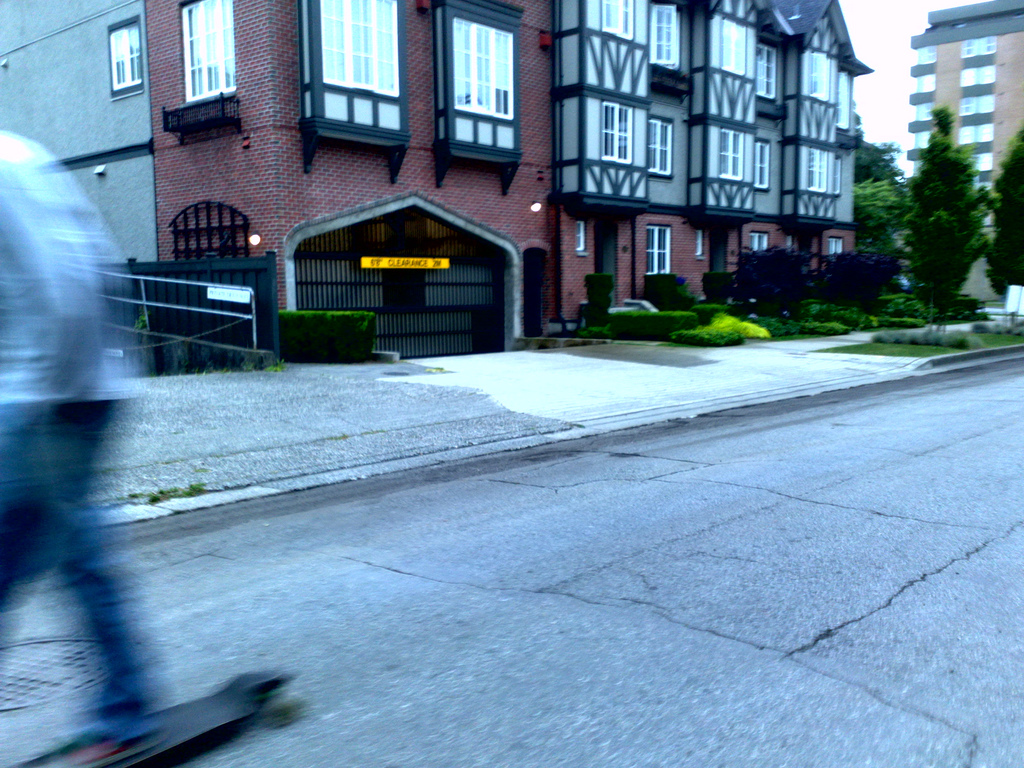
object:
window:
[646, 224, 671, 275]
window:
[695, 230, 703, 256]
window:
[577, 221, 586, 252]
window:
[109, 21, 144, 93]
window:
[600, 100, 632, 164]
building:
[0, 0, 874, 378]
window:
[647, 118, 672, 177]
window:
[718, 128, 743, 181]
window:
[751, 141, 771, 189]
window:
[810, 148, 829, 193]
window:
[748, 230, 767, 252]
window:
[829, 237, 845, 255]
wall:
[266, 0, 559, 248]